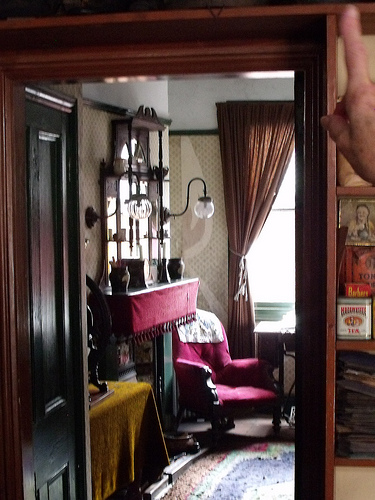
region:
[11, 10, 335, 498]
view through a doorway of an old fashioned room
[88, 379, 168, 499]
dark mustard colored table cloth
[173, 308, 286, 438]
a red armchair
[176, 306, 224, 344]
antimacassar over top of armchair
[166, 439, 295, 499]
multicolored rug on floor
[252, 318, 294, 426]
chair at a writing desk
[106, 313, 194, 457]
fireplace with decorative screen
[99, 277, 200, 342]
red fringed cloth hung on mantlepiece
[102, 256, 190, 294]
vases and clock on mantlepiece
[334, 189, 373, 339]
antique containers and a photograph on shelf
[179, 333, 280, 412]
the seat is red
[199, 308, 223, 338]
he clothiing is white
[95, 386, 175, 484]
the table clothe is yellow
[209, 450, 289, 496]
the carpet is ground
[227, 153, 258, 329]
the curtain is brown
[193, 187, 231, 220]
the bulb is round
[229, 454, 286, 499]
light is on the surface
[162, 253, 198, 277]
the vase is round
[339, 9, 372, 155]
finger is up in the air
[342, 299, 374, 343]
the container is mettalic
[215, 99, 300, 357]
brown curtain on window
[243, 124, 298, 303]
glowing light through window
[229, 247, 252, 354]
tie back on curtain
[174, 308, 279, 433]
red chair with cloth on back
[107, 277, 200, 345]
mantel with red cloth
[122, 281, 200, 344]
red cloth with tassels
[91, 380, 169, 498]
gold cloth on table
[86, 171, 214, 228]
two lights with curved poles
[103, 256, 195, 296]
vases on mantel top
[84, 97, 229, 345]
tan wallpaper covered wall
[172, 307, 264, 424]
the chair is red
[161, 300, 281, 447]
the chair is empty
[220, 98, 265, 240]
this is a curtain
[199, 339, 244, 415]
this is a chair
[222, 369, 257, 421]
the chair is red in color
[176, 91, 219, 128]
this is the wall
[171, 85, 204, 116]
the wall is white in color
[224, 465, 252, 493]
this is the floor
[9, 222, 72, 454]
this is the door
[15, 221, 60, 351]
the door is brown in color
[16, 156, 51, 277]
the door is wooden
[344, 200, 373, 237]
this is a picture